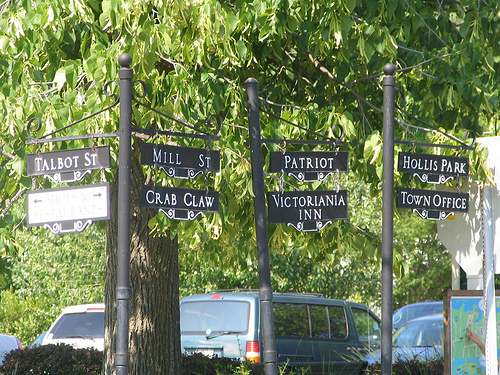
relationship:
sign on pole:
[24, 143, 113, 182] [103, 50, 137, 374]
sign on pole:
[136, 138, 227, 180] [103, 50, 137, 374]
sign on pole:
[136, 182, 223, 223] [103, 50, 137, 374]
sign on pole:
[267, 146, 352, 185] [238, 74, 286, 375]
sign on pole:
[267, 187, 351, 237] [238, 74, 286, 375]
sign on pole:
[394, 150, 473, 192] [373, 59, 402, 374]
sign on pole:
[395, 185, 471, 224] [373, 59, 402, 374]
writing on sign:
[32, 153, 100, 170] [24, 143, 113, 182]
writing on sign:
[150, 146, 215, 175] [136, 138, 227, 180]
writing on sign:
[143, 187, 214, 211] [136, 182, 223, 223]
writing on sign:
[281, 154, 335, 173] [267, 146, 352, 185]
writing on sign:
[270, 189, 346, 226] [267, 187, 351, 237]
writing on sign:
[400, 154, 469, 176] [394, 150, 473, 192]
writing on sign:
[400, 187, 468, 213] [395, 185, 471, 224]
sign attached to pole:
[24, 143, 113, 182] [103, 50, 137, 374]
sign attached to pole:
[136, 138, 227, 180] [103, 50, 137, 374]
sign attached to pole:
[136, 182, 223, 223] [103, 50, 137, 374]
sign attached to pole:
[267, 146, 352, 185] [238, 74, 286, 375]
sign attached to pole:
[267, 187, 351, 237] [238, 74, 286, 375]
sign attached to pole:
[394, 150, 473, 192] [373, 59, 402, 374]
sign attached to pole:
[395, 185, 471, 224] [373, 59, 402, 374]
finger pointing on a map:
[467, 327, 476, 338] [446, 290, 500, 374]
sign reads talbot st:
[24, 143, 113, 182] [32, 153, 100, 170]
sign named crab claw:
[136, 182, 223, 223] [143, 187, 214, 211]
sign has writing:
[267, 187, 351, 237] [270, 189, 346, 226]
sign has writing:
[395, 185, 471, 224] [400, 187, 468, 213]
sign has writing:
[394, 150, 473, 192] [400, 154, 469, 176]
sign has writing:
[136, 138, 227, 180] [150, 146, 215, 175]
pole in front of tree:
[103, 50, 137, 374] [0, 0, 497, 372]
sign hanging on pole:
[24, 143, 113, 182] [103, 50, 137, 374]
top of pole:
[118, 49, 135, 70] [103, 50, 137, 374]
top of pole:
[242, 76, 260, 92] [238, 74, 286, 375]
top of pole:
[381, 59, 397, 81] [373, 59, 402, 374]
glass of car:
[175, 296, 252, 341] [167, 288, 400, 374]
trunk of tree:
[97, 120, 189, 374] [0, 0, 497, 372]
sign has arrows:
[24, 180, 115, 240] [93, 190, 100, 201]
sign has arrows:
[24, 180, 115, 240] [31, 198, 43, 208]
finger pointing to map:
[467, 327, 476, 338] [446, 290, 500, 374]